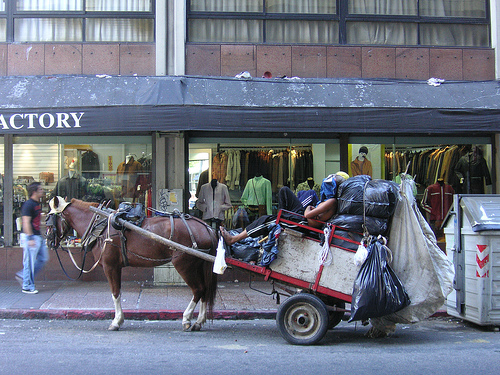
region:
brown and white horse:
[40, 194, 218, 331]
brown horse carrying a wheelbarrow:
[44, 189, 219, 333]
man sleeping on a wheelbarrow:
[217, 173, 347, 244]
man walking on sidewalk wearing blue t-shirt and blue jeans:
[17, 180, 52, 299]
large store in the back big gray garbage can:
[437, 195, 499, 330]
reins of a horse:
[69, 203, 224, 281]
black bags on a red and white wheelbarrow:
[330, 176, 404, 323]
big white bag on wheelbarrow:
[385, 185, 452, 328]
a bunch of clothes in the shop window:
[10, 138, 497, 249]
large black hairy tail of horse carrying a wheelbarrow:
[200, 246, 217, 322]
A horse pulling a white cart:
[37, 163, 456, 352]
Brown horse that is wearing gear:
[45, 188, 220, 338]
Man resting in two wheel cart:
[217, 168, 429, 345]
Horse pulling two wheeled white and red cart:
[40, 166, 456, 348]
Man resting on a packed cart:
[213, 159, 459, 347]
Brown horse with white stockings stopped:
[42, 182, 229, 336]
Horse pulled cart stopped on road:
[37, 164, 459, 349]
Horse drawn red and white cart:
[38, 163, 455, 348]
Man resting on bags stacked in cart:
[210, 160, 452, 349]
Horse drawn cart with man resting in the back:
[41, 162, 456, 350]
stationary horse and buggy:
[46, 167, 453, 344]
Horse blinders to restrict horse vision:
[42, 212, 61, 251]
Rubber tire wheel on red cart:
[273, 289, 328, 346]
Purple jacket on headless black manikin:
[193, 166, 233, 221]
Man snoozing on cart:
[215, 166, 350, 251]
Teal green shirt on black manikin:
[238, 165, 273, 217]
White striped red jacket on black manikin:
[419, 174, 461, 224]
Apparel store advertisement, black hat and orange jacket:
[345, 141, 385, 178]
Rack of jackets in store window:
[214, 142, 316, 177]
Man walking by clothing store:
[11, 176, 44, 299]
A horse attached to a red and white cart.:
[48, 193, 376, 343]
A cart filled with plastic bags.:
[219, 177, 456, 344]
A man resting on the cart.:
[218, 168, 348, 247]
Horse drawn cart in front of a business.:
[0, 5, 498, 372]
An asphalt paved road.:
[0, 316, 499, 374]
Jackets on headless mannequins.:
[193, 173, 274, 225]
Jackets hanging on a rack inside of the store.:
[384, 141, 494, 198]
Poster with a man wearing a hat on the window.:
[348, 140, 379, 177]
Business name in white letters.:
[0, 108, 85, 128]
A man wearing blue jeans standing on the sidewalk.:
[14, 181, 49, 298]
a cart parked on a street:
[18, 17, 487, 369]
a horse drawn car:
[25, 180, 385, 327]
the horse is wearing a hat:
[37, 183, 75, 242]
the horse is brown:
[22, 174, 251, 351]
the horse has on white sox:
[102, 272, 217, 334]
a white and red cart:
[249, 190, 380, 302]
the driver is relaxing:
[223, 179, 358, 258]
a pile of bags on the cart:
[339, 176, 442, 337]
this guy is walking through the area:
[9, 171, 54, 301]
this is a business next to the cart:
[18, 90, 497, 205]